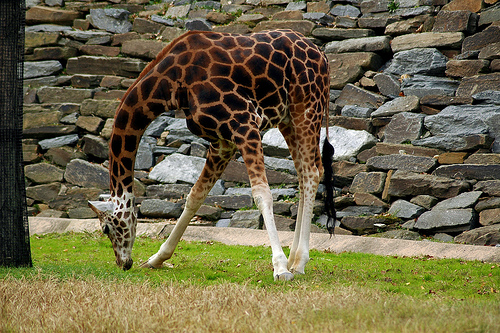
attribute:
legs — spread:
[241, 140, 291, 285]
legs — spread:
[127, 135, 228, 272]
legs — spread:
[291, 87, 318, 274]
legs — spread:
[279, 120, 309, 265]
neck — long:
[68, 32, 201, 194]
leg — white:
[145, 144, 237, 269]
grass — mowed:
[31, 235, 498, 300]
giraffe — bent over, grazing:
[87, 30, 334, 282]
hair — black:
[321, 137, 334, 238]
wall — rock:
[339, 13, 491, 200]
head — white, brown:
[98, 195, 133, 274]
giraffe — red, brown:
[87, 1, 340, 298]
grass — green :
[271, 283, 438, 312]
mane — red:
[98, 144, 125, 216]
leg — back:
[292, 109, 320, 278]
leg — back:
[280, 118, 302, 269]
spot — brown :
[264, 57, 287, 87]